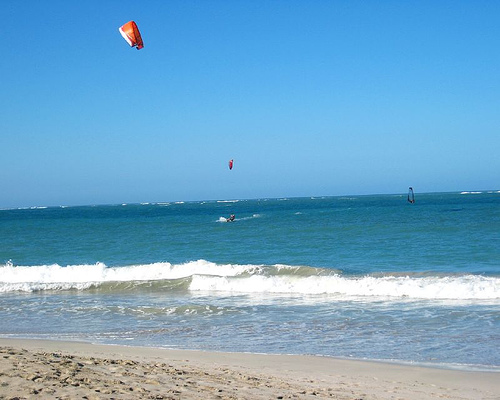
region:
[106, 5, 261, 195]
Enjoying kitesurfing with a red kite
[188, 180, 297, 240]
A motor boat doing kite surfing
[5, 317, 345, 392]
A sandy beach on coast line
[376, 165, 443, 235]
A bouey in the water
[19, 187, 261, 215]
White caps on the horizon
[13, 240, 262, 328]
Waves rolling in to shore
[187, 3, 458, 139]
Cloudless blue sky above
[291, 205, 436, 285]
The turquoise water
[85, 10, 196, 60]
A white stripe on the kite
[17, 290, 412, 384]
Shallow water of the beach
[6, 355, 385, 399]
a sandy beach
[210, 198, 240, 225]
a kite surfer on the water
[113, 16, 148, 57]
a kite used for kite surfing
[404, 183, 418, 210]
a windsurfer on the water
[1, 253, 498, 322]
waves breaking at the beach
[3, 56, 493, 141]
a clear blue sky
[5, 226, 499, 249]
blue green water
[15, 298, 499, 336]
grey foamy water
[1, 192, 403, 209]
waves cresting offshore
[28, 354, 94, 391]
tracks in the sand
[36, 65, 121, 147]
Sky is blue in color.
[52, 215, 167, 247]
Water is blue in color.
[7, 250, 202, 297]
Waves are white in color.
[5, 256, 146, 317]
Water is splashing.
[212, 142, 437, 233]
person are wake-boarding in sea.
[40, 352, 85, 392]
sand is brown color.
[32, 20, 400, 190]
Sky is clear with no clouds.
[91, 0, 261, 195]
Two balloons are seen.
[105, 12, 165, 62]
Balloon is red color.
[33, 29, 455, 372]
day time picture.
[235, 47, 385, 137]
sky is blue color.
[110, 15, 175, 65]
balloon is red color.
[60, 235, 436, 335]
waves is white color.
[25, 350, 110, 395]
sand is brown color.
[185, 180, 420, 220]
people are wake-boarding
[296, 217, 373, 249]
water is blue color.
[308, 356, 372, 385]
sand is wet due to water.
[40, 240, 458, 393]
day is bright sunny.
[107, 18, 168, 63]
an open parasail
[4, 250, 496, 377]
Waves on a beach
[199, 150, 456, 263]
Two people parasailing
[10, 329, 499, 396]
A sandy beach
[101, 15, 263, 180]
Two open parasails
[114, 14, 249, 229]
A man parasailing and another para-sail in background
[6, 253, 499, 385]
Waves rolling onto the beach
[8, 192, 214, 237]
White tops of waves out to sea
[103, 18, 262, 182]
Two parasails and a blue sky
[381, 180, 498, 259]
A recreational vessel on the ocean